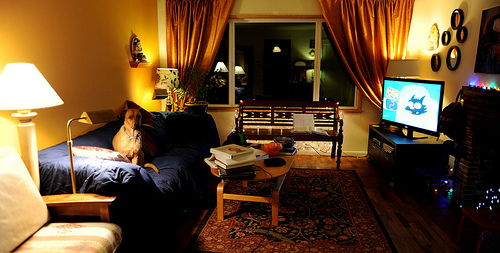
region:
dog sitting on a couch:
[84, 86, 213, 231]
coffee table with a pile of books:
[211, 118, 303, 235]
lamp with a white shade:
[0, 48, 73, 190]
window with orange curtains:
[160, 3, 415, 105]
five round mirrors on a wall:
[424, 0, 476, 82]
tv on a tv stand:
[370, 60, 461, 211]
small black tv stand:
[362, 125, 452, 210]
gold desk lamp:
[57, 100, 119, 210]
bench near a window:
[225, 53, 349, 163]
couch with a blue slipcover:
[32, 106, 213, 241]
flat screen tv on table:
[348, 43, 461, 156]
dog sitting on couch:
[19, 89, 236, 234]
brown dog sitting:
[95, 92, 180, 188]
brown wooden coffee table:
[202, 125, 309, 252]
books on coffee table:
[205, 127, 273, 200]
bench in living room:
[222, 87, 375, 184]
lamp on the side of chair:
[4, 49, 64, 220]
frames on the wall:
[420, 6, 485, 88]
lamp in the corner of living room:
[147, 54, 208, 129]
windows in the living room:
[151, 10, 383, 128]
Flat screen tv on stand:
[362, 55, 457, 160]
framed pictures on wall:
[420, 0, 481, 85]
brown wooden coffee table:
[195, 132, 316, 242]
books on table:
[185, 122, 286, 207]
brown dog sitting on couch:
[107, 92, 177, 193]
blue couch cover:
[35, 83, 222, 251]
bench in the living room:
[227, 100, 388, 160]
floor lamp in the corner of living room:
[365, 50, 450, 152]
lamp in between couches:
[0, 50, 90, 213]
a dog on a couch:
[54, 52, 241, 242]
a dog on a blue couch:
[67, 41, 217, 227]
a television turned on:
[352, 45, 474, 167]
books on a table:
[196, 96, 354, 237]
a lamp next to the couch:
[2, 45, 196, 240]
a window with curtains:
[154, 3, 468, 148]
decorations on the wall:
[404, 6, 497, 96]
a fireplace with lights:
[436, 64, 499, 188]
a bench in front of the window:
[222, 82, 403, 210]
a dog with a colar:
[71, 52, 206, 205]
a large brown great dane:
[106, 102, 171, 175]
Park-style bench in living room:
[224, 95, 351, 143]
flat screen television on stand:
[371, 70, 446, 143]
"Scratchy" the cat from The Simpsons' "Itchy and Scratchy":
[398, 86, 428, 117]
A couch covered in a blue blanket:
[27, 108, 223, 236]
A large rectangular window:
[166, 5, 365, 117]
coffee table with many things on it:
[206, 137, 304, 234]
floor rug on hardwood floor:
[176, 145, 396, 250]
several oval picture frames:
[421, 4, 471, 74]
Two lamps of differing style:
[0, 62, 125, 215]